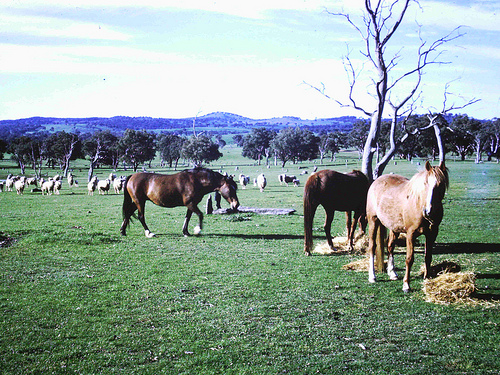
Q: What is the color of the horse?
A: Brown.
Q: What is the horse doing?
A: Standing.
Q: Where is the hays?
A: In the grass.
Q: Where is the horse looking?
A: Towards the left.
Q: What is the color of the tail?
A: Dark brown.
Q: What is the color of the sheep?
A: Brown.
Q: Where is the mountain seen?
A: Behind the trees.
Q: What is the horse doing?
A: Standing.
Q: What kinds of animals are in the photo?
A: Horses and sheep.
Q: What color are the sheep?
A: White.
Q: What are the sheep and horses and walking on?
A: Grass.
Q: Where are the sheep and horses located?
A: Green field.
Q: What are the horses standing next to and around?
A: Tree.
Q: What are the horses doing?
A: Feeding.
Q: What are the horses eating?
A: Small piles of hay.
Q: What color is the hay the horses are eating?
A: Tan.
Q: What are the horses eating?
A: Hay.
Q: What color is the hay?
A: Brown.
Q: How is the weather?
A: Overcast.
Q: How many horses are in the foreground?
A: Two.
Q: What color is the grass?
A: Green.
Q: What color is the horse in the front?
A: Brown.